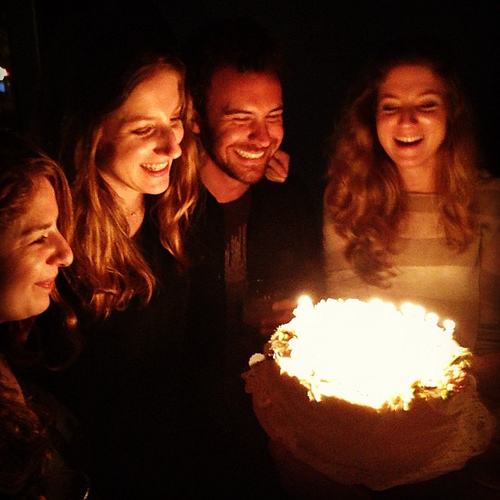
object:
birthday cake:
[241, 294, 499, 495]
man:
[194, 43, 328, 437]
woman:
[0, 152, 89, 498]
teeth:
[237, 153, 273, 160]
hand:
[261, 151, 290, 183]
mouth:
[389, 133, 427, 152]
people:
[321, 56, 499, 392]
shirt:
[0, 368, 92, 500]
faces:
[204, 68, 284, 187]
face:
[373, 66, 461, 173]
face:
[114, 77, 184, 198]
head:
[369, 57, 452, 165]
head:
[81, 51, 186, 196]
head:
[0, 152, 74, 326]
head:
[184, 36, 283, 189]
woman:
[43, 54, 288, 436]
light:
[284, 283, 462, 407]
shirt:
[320, 186, 498, 359]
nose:
[45, 230, 73, 270]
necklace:
[105, 193, 144, 220]